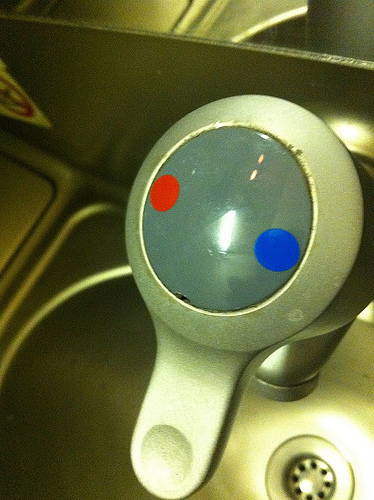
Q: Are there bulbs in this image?
A: No, there are no bulbs.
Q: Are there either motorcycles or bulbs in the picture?
A: No, there are no bulbs or motorcycles.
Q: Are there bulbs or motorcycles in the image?
A: No, there are no bulbs or motorcycles.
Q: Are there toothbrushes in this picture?
A: No, there are no toothbrushes.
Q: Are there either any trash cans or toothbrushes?
A: No, there are no toothbrushes or trash cans.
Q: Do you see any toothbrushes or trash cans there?
A: No, there are no toothbrushes or trash cans.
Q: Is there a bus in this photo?
A: No, there are no buses.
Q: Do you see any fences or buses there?
A: No, there are no buses or fences.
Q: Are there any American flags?
A: No, there are no American flags.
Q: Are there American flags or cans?
A: No, there are no American flags or cans.